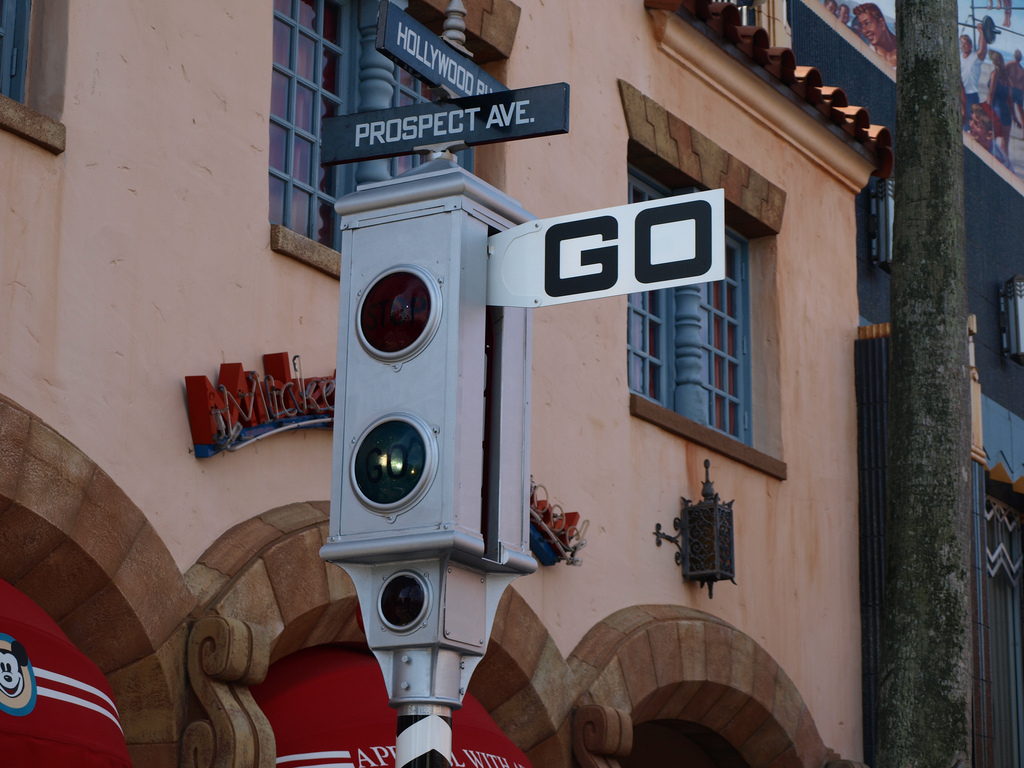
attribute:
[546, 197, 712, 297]
word — black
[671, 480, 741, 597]
lamp — black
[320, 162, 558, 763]
post — grey, sign post